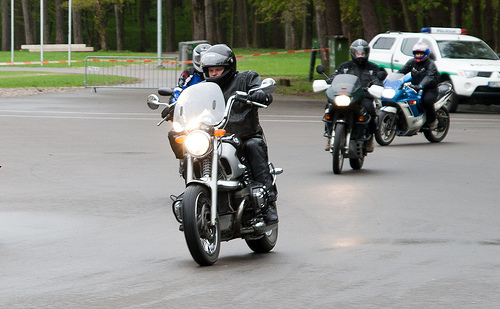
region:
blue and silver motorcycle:
[369, 71, 454, 144]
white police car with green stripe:
[364, 25, 495, 99]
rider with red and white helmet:
[393, 37, 438, 130]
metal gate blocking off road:
[79, 58, 192, 98]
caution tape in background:
[1, 43, 335, 68]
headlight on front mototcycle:
[178, 127, 212, 160]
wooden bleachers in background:
[16, 43, 103, 56]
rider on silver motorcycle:
[192, 36, 276, 232]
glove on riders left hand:
[249, 88, 272, 103]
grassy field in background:
[0, 43, 310, 93]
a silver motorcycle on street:
[148, 47, 283, 261]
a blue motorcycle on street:
[373, 43, 453, 145]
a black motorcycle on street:
[308, 37, 390, 174]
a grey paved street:
[1, 98, 498, 305]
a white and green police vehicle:
[364, 25, 498, 109]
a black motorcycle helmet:
[344, 38, 373, 65]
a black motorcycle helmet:
[201, 41, 237, 88]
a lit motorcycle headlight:
[184, 128, 210, 155]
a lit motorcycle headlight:
[331, 91, 348, 106]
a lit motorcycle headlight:
[382, 86, 393, 96]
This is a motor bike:
[154, 42, 300, 285]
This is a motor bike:
[309, 25, 385, 187]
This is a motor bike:
[377, 25, 471, 159]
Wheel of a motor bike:
[170, 172, 229, 274]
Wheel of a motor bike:
[233, 165, 309, 256]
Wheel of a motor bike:
[325, 112, 350, 177]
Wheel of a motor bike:
[350, 115, 375, 185]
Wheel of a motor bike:
[380, 105, 406, 160]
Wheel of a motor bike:
[419, 100, 461, 150]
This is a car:
[352, 16, 494, 124]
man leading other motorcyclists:
[169, 40, 282, 260]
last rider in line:
[377, 28, 454, 149]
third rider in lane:
[302, 30, 390, 175]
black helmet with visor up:
[195, 44, 240, 82]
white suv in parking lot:
[354, 25, 495, 97]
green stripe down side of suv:
[376, 55, 403, 74]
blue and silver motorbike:
[382, 70, 457, 137]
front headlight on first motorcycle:
[177, 127, 211, 156]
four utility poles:
[4, 2, 172, 64]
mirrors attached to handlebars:
[145, 76, 277, 116]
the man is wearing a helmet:
[198, 42, 236, 88]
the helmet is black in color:
[198, 43, 238, 88]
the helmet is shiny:
[201, 43, 236, 89]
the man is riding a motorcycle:
[160, 42, 280, 255]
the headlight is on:
[180, 130, 207, 155]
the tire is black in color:
[176, 185, 222, 266]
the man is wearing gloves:
[245, 85, 261, 100]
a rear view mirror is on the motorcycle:
[246, 75, 271, 95]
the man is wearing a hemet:
[413, 40, 428, 55]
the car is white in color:
[368, 27, 498, 107]